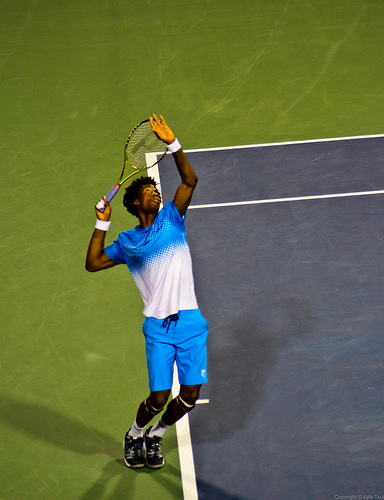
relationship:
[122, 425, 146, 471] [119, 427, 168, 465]
shoes on feet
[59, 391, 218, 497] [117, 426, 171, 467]
shoes on feet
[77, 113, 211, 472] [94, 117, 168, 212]
man swinging racket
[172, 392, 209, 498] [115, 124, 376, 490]
white line on tennis court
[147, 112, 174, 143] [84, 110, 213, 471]
hand of man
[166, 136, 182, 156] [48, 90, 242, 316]
band on player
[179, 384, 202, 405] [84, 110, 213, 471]
knee on man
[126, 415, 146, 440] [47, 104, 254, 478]
sock on tennis player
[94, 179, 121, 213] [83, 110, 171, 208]
handle of racket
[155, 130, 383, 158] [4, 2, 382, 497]
scuff mark on tennis court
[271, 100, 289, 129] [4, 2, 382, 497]
scuff mark on tennis court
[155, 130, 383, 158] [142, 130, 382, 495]
scuff mark on tennis court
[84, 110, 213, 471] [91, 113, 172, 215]
man swinging racket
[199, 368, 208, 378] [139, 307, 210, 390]
symbol on shorts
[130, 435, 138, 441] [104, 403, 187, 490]
symbol on shoes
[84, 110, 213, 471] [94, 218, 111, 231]
man wearing band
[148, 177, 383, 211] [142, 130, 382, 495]
line on tennis court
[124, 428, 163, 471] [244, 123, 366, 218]
feet on court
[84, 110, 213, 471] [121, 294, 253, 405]
man wearing shorts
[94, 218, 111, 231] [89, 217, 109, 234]
band on wrist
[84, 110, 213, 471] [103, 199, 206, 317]
man wearing shirt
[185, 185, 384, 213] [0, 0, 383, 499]
line on tennis court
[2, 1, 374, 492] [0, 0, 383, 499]
surface of tennis court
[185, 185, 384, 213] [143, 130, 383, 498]
line on court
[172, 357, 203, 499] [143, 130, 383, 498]
white line on court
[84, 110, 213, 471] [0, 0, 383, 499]
man on tennis court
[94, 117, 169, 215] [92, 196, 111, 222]
racket in hand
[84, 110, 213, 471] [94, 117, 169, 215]
man with racket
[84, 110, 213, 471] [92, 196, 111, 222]
man with hand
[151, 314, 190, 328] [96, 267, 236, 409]
strings on shorts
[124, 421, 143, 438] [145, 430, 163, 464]
sock on foot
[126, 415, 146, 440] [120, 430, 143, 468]
sock on foot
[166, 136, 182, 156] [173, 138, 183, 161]
band on wrist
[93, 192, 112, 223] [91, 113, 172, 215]
hand gripping a racket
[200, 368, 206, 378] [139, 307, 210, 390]
symbol on shorts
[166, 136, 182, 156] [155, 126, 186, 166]
band on wrist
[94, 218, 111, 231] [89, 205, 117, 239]
band on wrist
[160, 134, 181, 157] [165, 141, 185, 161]
band on wrist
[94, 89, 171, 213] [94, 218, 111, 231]
racket in band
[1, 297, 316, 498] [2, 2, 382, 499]
shadow on ground